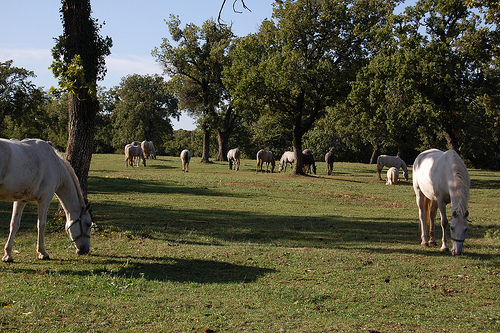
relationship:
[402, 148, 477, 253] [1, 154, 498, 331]
white horse in a field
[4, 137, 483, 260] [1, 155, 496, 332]
white horses in grass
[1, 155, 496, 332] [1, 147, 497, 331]
grass on ground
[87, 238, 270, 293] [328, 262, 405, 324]
shadow on grass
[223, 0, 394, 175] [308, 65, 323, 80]
tree with leaf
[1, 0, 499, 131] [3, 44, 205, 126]
blue sky with clouds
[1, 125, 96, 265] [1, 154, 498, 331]
whitehorse in field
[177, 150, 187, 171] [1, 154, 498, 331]
horse in field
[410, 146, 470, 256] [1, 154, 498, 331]
white horse in field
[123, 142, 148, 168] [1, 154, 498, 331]
horse grazing in field